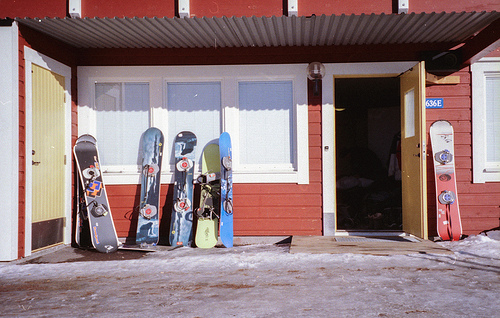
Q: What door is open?
A: The one on the right.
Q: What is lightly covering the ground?
A: Snow.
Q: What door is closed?
A: One on the left.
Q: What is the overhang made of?
A: Sheet metal.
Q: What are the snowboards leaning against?
A: Building.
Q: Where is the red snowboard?
A: Behind door on right.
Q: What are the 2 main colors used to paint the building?
A: Red, and white.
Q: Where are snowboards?
A: Against the building.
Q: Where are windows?
A: On the building.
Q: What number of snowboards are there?
A: Six.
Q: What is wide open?
A: The door.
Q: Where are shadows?
A: On the building.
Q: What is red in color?
A: The building.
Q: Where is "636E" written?
A: On a blue sign.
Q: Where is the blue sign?
A: Next to the door.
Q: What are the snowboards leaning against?
A: Building.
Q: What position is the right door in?
A: Open.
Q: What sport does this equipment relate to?
A: Snowboarding.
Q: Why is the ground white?
A: There is snow.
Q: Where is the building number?
A: On the right.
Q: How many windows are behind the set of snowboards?
A: 3.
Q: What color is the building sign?
A: Blue.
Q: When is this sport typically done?
A: Winter.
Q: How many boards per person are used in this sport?
A: 1.